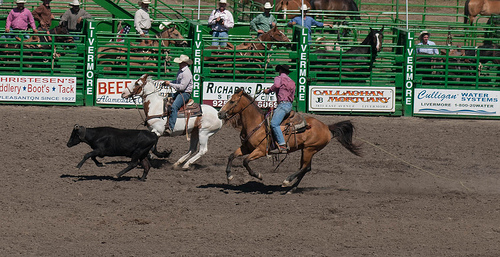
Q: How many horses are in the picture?
A: Three.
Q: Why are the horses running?
A: It's a Rodeo.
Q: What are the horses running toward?
A: A bull.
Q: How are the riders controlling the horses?
A: Reins.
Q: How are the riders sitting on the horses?
A: Using a saddle.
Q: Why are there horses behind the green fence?
A: Separate them.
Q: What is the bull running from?
A: Horses.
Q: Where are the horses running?
A: A dirt Rodeo.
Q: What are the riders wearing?
A: Cowboy hats.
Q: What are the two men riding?
A: Horses.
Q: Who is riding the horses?
A: Cowboys.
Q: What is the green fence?
A: Tall.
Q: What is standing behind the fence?
A: The man.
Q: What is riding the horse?
A: The man.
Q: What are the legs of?
A: The horse.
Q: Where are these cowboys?
A: An arena.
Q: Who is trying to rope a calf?
A: Two cowboys.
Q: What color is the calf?
A: Black.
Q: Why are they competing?
A: It's a rodeo.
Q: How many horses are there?
A: Two.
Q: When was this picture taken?
A: During the day.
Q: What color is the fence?
A: Green.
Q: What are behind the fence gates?
A: Horses and riders.